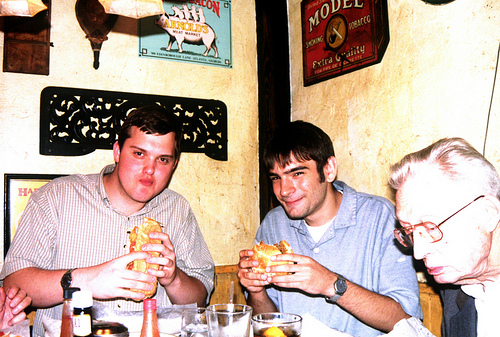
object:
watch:
[324, 272, 348, 304]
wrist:
[317, 265, 353, 305]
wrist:
[55, 267, 86, 304]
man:
[0, 103, 216, 336]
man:
[384, 134, 498, 290]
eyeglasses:
[392, 195, 489, 249]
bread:
[122, 214, 165, 303]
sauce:
[66, 290, 99, 337]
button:
[312, 247, 321, 254]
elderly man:
[384, 135, 499, 287]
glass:
[206, 300, 253, 335]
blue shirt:
[252, 179, 424, 335]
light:
[72, 0, 165, 71]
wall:
[0, 0, 288, 310]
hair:
[117, 104, 188, 150]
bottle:
[137, 295, 164, 337]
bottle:
[58, 282, 81, 337]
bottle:
[71, 288, 95, 337]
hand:
[263, 252, 327, 297]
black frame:
[4, 172, 9, 259]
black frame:
[2, 172, 70, 179]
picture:
[1, 2, 496, 334]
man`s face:
[397, 169, 498, 283]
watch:
[56, 267, 79, 292]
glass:
[249, 310, 305, 336]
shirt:
[247, 179, 427, 337]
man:
[237, 120, 423, 336]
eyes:
[292, 170, 305, 178]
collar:
[96, 162, 160, 221]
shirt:
[4, 159, 223, 337]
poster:
[298, 0, 392, 89]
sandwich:
[251, 239, 295, 283]